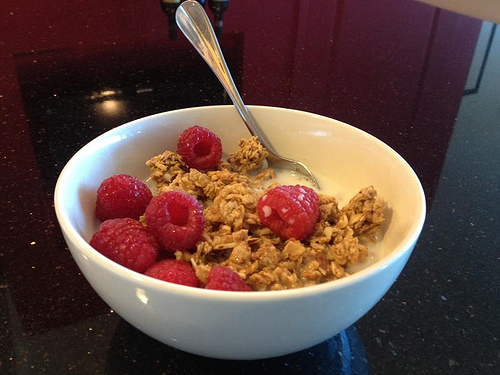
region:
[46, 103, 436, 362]
white ceramic bowl filled with granola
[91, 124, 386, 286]
brown crunchy granola with fresh red raspberries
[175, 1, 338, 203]
silver spoon in white bowl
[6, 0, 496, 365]
black granite counter with white bowl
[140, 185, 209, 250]
juicy red raspberry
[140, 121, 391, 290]
white milk with cereal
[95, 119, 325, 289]
eight raspberries on granola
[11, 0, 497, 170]
reflection of red cabinets and stove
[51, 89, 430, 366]
round white ceramic bowl with breakfast food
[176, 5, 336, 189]
silver spoon covered in milk in granola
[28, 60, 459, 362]
this is a bowl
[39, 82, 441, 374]
the bowl is white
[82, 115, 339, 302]
raspberries in a bowl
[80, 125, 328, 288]
the raspberries are red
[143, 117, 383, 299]
granola in a bowl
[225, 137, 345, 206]
milk in the bowl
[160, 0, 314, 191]
this is a spoon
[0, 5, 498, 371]
a bowl on a counter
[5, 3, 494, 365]
the counter is black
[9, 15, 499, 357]
white flecks in counter top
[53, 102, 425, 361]
a round white bowl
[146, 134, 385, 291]
granola in the bowl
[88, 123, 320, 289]
raspberries in the bowl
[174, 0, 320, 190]
metal spoon in the bowl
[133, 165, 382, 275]
milk in the bowl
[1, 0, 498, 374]
a granite counter top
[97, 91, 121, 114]
reflection of light on the counter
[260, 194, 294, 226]
milk on a raspberry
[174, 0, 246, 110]
handle of the spoon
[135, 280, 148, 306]
light reflecting off the bowl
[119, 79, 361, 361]
a white bowl with ceral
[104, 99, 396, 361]
a white bowl with rasberries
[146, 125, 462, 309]
a whtie bowl with milk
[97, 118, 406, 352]
a white bowl with spoon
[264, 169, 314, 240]
rasberry in a bowl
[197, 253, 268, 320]
rasberry in a bowl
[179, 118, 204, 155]
rasberry in a bowl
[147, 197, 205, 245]
rasberry in a bowl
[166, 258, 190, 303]
rasberry in a bowl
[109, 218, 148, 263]
rasberry in a bowl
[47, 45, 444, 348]
a bowl of ceral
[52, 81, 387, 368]
a white bowl of ceral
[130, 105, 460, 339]
raspberries in a white bowl